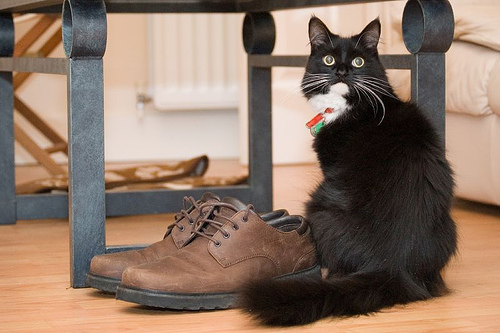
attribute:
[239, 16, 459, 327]
cat — black, surprised, wide eyed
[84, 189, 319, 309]
shoes — brown, dark brown, leather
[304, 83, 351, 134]
toy — white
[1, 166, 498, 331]
floor — hard wood, real wood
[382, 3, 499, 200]
couch — cream colored, white, beige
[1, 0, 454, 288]
table — metal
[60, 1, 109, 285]
leg — metal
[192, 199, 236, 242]
shoestring — brown, tied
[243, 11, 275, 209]
leg — metal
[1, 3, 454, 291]
legs — metal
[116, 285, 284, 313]
sole of shoe — rubber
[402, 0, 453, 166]
leg — black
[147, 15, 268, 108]
radiator — white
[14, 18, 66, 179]
legs — wooden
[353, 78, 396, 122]
whiskers — white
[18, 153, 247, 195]
rug — rolled up